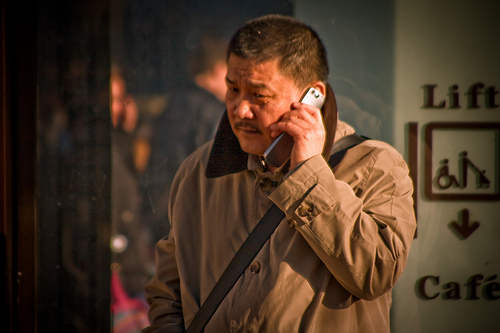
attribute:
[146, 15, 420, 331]
man — asian, talkig, speaking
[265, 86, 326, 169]
phone — older model, flip phone, silver, grey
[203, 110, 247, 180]
collar — brown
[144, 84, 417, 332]
coat — brown, long, tan, collared, light brown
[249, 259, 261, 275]
button — brown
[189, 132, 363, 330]
strap — crossbody, leather, black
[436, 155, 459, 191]
wheelchair logo — printed, handicapped logo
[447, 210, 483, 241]
arrow — facing down, pointing down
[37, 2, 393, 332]
window — reflective, glass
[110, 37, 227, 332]
people — blurry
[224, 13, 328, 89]
hair — short, black, spikey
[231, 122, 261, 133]
mustache — dark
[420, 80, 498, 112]
lift — brown, printed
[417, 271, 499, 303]
cafã© — brow, printed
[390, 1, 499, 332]
sign — for food, for accessibilit